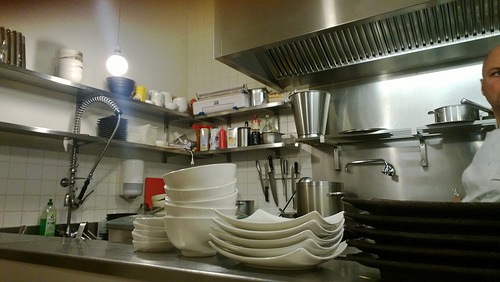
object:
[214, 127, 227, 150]
bottle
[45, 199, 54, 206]
tope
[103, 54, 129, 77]
light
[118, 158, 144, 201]
dispenser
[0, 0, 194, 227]
wall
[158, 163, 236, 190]
bowl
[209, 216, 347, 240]
plate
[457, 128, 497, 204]
coat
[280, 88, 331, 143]
pot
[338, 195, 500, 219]
plate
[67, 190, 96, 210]
faucet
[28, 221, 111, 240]
sink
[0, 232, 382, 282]
counter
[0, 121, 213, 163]
shelf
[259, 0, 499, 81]
vent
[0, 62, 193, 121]
shelves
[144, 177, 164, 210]
cutting board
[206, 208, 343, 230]
dishes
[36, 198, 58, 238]
dish soap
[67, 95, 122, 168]
hose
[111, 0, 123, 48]
cord